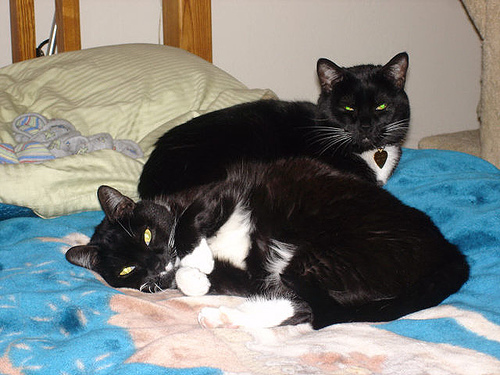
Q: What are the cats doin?
A: Resting.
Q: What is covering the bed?
A: Beadspread.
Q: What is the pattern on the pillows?
A: Lines.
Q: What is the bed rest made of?
A: Wood.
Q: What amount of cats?
A: Two.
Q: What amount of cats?
A: Two.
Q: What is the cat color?
A: Black.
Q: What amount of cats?
A: Two.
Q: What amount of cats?
A: Two.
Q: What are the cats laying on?
A: A blue bedspread.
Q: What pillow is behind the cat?
A: The ones in front the headboard.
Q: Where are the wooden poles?
A: Behind the pillow.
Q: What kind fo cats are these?
A: Black cats.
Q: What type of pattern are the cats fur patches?
A: White spots.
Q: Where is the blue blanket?
A: Below the cats.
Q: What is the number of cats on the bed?
A: Two.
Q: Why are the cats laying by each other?
A: To cuddle for warmth.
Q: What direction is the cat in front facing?
A: Towards the camera.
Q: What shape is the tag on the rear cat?
A: A heart.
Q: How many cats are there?
A: Two.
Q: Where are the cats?
A: On the bed.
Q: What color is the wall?
A: White.